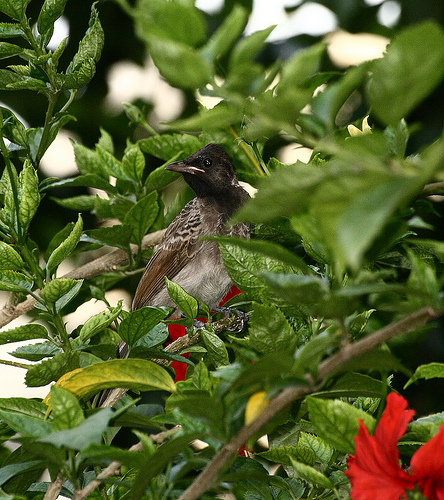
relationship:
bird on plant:
[117, 141, 262, 346] [3, 4, 429, 499]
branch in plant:
[146, 294, 433, 498] [3, 4, 429, 499]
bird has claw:
[117, 141, 262, 346] [204, 301, 250, 336]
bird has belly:
[117, 141, 262, 346] [157, 233, 255, 315]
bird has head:
[117, 141, 262, 346] [156, 139, 241, 210]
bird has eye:
[117, 141, 262, 346] [202, 157, 212, 170]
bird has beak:
[117, 141, 262, 346] [165, 157, 207, 173]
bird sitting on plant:
[117, 141, 262, 346] [3, 4, 429, 499]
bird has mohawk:
[117, 141, 262, 346] [198, 139, 233, 162]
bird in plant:
[117, 141, 262, 346] [3, 4, 429, 499]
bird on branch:
[117, 141, 262, 346] [43, 297, 283, 499]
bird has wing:
[117, 141, 262, 346] [123, 196, 208, 301]